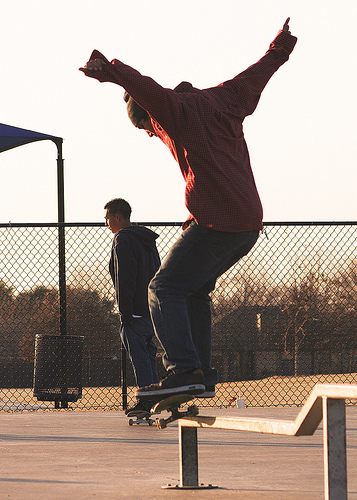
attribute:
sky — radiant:
[23, 24, 342, 214]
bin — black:
[30, 332, 84, 402]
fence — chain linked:
[2, 217, 352, 412]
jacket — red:
[176, 140, 255, 195]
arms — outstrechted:
[82, 22, 355, 110]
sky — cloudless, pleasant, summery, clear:
[3, 1, 356, 294]